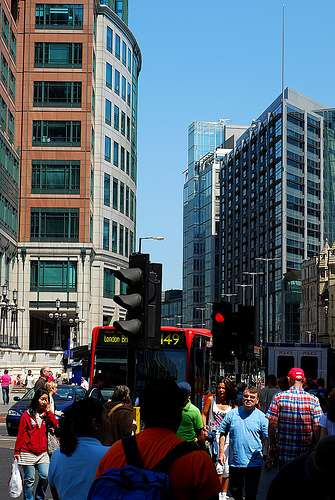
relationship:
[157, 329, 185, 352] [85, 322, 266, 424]
149 written on bus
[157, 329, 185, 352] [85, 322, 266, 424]
149 on front of bus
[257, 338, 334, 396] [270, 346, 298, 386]
van has door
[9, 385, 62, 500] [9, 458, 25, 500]
woman carrying bag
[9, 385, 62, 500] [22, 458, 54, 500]
woman inside of jeans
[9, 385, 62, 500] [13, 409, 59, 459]
woman wearing jacket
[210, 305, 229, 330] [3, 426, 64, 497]
stoplight in street